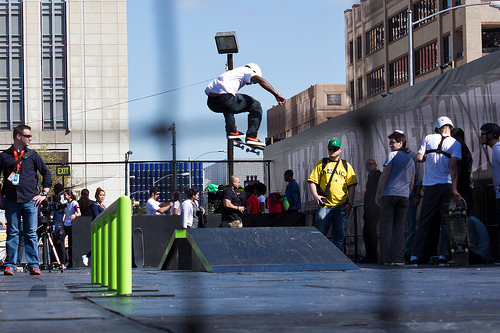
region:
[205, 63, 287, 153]
skateboarder in the air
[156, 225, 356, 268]
black skateboard ramp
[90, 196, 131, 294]
green railing in skateboard park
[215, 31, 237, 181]
metal light post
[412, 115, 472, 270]
skateboarder holding a skateboard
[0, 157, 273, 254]
fence around skateboard park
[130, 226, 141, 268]
skateboard leaning against black wall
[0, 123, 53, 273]
man watching skateboarder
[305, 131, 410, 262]
several men watching skateboarder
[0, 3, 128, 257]
concrete building near skateboard park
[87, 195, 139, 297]
light green rail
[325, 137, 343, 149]
green hat on a man's head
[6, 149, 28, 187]
red lanyard around a man's neck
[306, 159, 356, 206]
yellow shirt on a man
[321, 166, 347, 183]
graphic on a yellow shirt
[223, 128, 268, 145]
black and red nikes on a skater's foot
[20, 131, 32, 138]
shades over a man's eyes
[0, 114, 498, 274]
group of people standing around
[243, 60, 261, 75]
white helmet on a skater's head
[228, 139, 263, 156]
four wheels on a skateboard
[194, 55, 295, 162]
Skateboarder in the air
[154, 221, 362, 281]
A two-sided wood ramp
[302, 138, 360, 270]
A man wearing a yellow shirt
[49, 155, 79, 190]
Black and yellow exit sign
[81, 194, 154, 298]
Green metal rail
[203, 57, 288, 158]
Skateboarder wearing white shirt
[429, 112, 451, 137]
White helmet worn by person standing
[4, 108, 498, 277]
Crowd of people watching the skateboarder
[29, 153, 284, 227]
Fence behind the crowd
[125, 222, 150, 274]
Skateboard leaning against wall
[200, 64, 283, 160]
Man on a skateboard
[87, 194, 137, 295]
Bright green metal rail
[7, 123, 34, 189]
Man wearing id on red lanyard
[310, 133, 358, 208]
Man wearing green cap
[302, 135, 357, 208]
Man wearing yellow shirt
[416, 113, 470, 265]
Male holding a skateboard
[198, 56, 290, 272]
Man jumping a ramp on a skateboard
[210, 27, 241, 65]
Large arena light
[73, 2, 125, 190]
Tall white building in background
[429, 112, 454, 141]
Male wearing a white helmet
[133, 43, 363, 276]
Skateboarder jumping through the air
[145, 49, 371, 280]
man performs a skateboarding trick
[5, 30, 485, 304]
man skateboards while others watch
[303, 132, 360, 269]
a man with a yellow shirt and green cap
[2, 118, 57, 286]
man with a blue shirt and blue jeans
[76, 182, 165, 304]
bright green railing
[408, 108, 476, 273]
man in white shirt holding a skateboard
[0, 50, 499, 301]
urban skatepark with many people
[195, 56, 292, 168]
man in white shirt and blue jeans flying through the air on a skateboard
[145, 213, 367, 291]
Black and green skateboard ramp